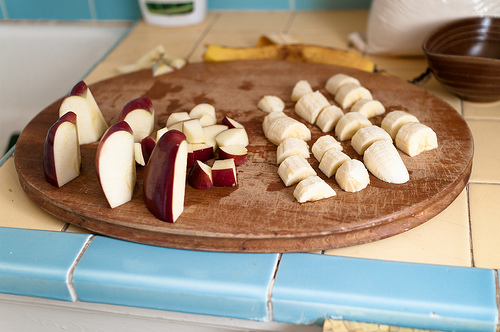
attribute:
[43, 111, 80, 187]
apple — cut up, unpeeled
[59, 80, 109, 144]
apple — cut up, unpeeled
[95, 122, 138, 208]
apple — cut up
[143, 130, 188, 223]
apple — cut up, red, unpeeled, upright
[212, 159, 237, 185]
apple — cut up, square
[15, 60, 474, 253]
board — round, wooden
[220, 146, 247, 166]
apple — cut up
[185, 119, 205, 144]
apple — cut up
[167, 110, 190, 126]
apple — cut up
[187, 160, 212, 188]
apple — unpeeled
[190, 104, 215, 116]
apple — cut up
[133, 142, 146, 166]
apple — cut up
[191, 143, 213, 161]
apple — cut up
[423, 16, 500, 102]
bowl — brown, pottery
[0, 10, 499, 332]
counter — tiled, blue, cream, white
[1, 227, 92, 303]
tile — blue, cream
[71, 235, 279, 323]
tile — blue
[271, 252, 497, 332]
tile — blue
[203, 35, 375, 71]
peel — yellow, banana peel, empty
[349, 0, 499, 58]
bag — white, plastic, clear, flour bag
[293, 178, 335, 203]
banana — sliced, small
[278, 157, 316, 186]
banana — sliced, lined up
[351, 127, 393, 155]
banana — sliced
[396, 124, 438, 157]
banana — sliced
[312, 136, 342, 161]
banana — sliced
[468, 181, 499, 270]
tile — white, blue, cream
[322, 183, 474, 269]
tile — white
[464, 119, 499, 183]
tile — white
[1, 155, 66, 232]
tile — white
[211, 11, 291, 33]
tile — white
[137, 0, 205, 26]
bottle — green, white, plastic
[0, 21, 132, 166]
sink — porcelain